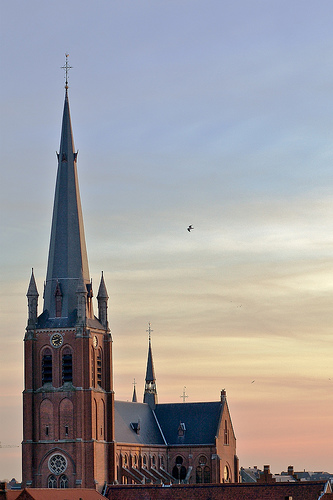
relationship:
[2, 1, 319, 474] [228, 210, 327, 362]
sky has clouds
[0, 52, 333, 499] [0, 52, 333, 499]
building are behind building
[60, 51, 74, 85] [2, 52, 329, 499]
cross on top of building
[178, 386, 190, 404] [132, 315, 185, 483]
cross dance right of building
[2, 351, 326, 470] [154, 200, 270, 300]
bands are in sky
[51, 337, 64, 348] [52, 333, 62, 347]
number on clock face